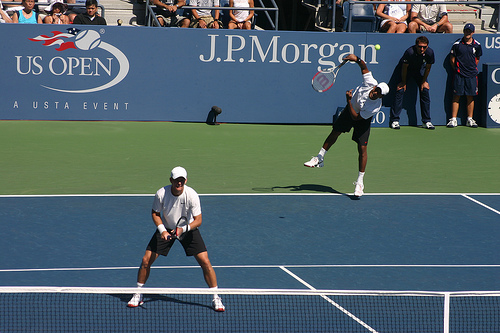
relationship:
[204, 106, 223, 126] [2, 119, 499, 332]
object on court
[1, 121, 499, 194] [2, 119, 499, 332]
asphalt on court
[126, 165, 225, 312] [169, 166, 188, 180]
player wearing a cap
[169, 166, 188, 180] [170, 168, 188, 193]
cap on head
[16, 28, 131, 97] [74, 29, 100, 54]
logo with a ball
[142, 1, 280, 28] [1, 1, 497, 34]
railing in stands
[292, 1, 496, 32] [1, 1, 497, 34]
railing in stands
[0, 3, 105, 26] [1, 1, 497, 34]
railing in stands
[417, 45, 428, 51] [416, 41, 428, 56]
sunglasses on face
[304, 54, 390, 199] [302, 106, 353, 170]
man has a raised leg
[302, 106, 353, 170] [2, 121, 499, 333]
leg off of ground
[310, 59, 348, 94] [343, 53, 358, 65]
racket in a hand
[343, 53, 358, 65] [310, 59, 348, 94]
hand holding racket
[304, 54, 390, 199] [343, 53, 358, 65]
player has a hand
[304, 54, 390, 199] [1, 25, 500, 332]
man playing tennis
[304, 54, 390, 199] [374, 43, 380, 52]
man serving a ball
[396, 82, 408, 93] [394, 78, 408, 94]
hand on knee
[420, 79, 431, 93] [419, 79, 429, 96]
hand on knee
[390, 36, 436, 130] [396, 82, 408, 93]
man has a hand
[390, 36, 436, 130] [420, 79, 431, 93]
man has a hand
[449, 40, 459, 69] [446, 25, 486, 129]
arm behind man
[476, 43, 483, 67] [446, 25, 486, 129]
arm behind man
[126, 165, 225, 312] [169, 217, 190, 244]
player holding racket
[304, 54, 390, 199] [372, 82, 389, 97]
man wearing cap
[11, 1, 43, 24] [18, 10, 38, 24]
woman wearing top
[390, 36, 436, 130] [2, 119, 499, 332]
man on court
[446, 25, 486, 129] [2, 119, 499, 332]
man on court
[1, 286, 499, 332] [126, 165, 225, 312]
net in front of player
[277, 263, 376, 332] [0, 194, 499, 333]
white line on court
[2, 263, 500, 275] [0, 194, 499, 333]
white line on court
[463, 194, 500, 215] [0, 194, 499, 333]
white line on court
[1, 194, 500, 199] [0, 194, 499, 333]
white line on court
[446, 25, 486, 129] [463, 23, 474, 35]
man wearing cap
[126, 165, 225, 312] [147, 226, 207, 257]
player wearing shorts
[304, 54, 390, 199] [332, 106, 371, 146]
man wearing shorts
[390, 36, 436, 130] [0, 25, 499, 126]
man next to wall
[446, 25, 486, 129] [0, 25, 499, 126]
man next to wall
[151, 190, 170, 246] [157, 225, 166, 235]
arm has band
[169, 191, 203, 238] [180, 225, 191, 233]
arm has band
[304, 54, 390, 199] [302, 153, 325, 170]
man wearing shoe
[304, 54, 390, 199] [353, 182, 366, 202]
man wearing shoe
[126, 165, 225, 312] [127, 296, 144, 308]
player wearing shoe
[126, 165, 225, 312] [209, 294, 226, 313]
player wearing shoe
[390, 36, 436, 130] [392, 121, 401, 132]
man wearing shoe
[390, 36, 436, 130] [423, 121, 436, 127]
man wearing shoe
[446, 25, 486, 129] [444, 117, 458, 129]
man wearing shoe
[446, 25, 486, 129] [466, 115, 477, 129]
man wearing shoe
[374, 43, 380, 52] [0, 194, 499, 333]
ball over court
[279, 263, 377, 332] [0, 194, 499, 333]
line on court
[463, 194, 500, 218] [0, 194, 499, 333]
line on court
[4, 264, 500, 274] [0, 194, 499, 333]
line on court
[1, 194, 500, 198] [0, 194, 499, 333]
line on court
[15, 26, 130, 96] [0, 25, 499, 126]
advertisement on wall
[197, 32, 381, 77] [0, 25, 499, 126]
advertisement on wall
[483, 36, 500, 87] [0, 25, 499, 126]
advertisement on wall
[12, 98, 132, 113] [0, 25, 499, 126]
advertisement on wall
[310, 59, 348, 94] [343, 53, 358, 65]
racket in hand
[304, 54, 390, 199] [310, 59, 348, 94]
man has a racket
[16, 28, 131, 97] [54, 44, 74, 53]
logo has red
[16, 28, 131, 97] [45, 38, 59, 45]
logo has red